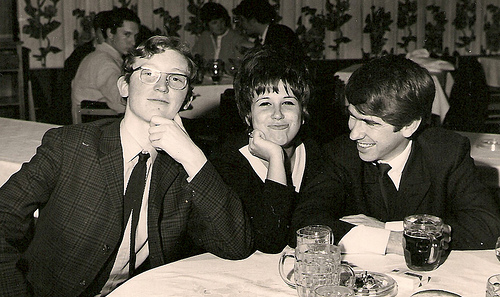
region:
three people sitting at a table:
[67, 24, 496, 273]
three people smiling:
[60, 22, 458, 222]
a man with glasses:
[53, 32, 225, 192]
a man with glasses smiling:
[74, 29, 225, 199]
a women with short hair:
[219, 29, 343, 209]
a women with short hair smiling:
[207, 32, 329, 188]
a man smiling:
[314, 40, 462, 181]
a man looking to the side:
[314, 38, 469, 233]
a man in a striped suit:
[10, 7, 249, 259]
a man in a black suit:
[332, 35, 486, 244]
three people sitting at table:
[56, 34, 467, 281]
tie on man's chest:
[95, 144, 155, 271]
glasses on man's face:
[131, 61, 191, 97]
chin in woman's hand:
[240, 124, 289, 176]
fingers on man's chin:
[145, 109, 188, 140]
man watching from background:
[98, 4, 140, 66]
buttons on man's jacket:
[69, 239, 111, 291]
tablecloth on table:
[435, 74, 461, 122]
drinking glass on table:
[397, 211, 452, 278]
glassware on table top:
[288, 219, 352, 293]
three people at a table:
[0, 34, 499, 294]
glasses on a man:
[125, 64, 194, 94]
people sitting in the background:
[89, 3, 293, 45]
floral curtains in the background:
[319, 6, 499, 49]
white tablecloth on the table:
[154, 261, 279, 294]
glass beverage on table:
[396, 210, 458, 278]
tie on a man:
[98, 144, 153, 294]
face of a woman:
[231, 39, 324, 152]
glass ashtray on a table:
[347, 263, 399, 295]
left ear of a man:
[400, 103, 427, 143]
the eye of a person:
[141, 63, 161, 84]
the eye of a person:
[167, 71, 179, 86]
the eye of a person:
[260, 96, 271, 106]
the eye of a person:
[277, 95, 294, 110]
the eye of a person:
[361, 115, 376, 127]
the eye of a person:
[346, 110, 351, 120]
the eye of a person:
[120, 30, 125, 35]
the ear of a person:
[115, 72, 130, 93]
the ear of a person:
[397, 110, 422, 140]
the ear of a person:
[103, 22, 115, 39]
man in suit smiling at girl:
[308, 78, 490, 240]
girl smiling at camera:
[196, 51, 338, 230]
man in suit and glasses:
[29, 52, 224, 294]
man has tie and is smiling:
[42, 35, 237, 282]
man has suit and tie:
[304, 63, 474, 255]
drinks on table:
[391, 208, 466, 265]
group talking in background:
[51, 1, 279, 78]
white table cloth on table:
[134, 260, 226, 285]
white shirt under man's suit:
[100, 143, 170, 275]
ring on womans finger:
[238, 125, 306, 172]